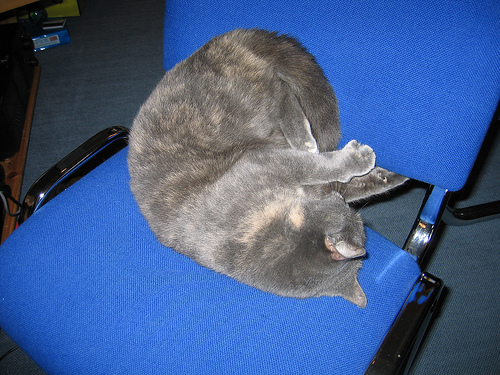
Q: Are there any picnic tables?
A: No, there are no picnic tables.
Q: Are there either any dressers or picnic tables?
A: No, there are no picnic tables or dressers.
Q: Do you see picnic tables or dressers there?
A: No, there are no picnic tables or dressers.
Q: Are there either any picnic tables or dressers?
A: No, there are no picnic tables or dressers.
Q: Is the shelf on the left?
A: Yes, the shelf is on the left of the image.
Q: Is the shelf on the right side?
A: No, the shelf is on the left of the image.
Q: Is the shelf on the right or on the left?
A: The shelf is on the left of the image.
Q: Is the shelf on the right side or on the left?
A: The shelf is on the left of the image.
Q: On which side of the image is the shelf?
A: The shelf is on the left of the image.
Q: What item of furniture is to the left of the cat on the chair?
A: The piece of furniture is a shelf.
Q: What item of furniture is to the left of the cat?
A: The piece of furniture is a shelf.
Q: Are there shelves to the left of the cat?
A: Yes, there is a shelf to the left of the cat.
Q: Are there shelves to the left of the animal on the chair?
A: Yes, there is a shelf to the left of the cat.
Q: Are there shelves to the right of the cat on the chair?
A: No, the shelf is to the left of the cat.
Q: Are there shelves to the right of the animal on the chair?
A: No, the shelf is to the left of the cat.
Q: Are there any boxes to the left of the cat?
A: No, there is a shelf to the left of the cat.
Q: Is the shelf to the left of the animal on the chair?
A: Yes, the shelf is to the left of the cat.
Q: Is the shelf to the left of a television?
A: No, the shelf is to the left of the cat.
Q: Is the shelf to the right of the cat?
A: No, the shelf is to the left of the cat.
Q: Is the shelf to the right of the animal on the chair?
A: No, the shelf is to the left of the cat.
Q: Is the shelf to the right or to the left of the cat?
A: The shelf is to the left of the cat.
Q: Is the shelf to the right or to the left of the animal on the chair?
A: The shelf is to the left of the cat.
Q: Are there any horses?
A: No, there are no horses.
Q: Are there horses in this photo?
A: No, there are no horses.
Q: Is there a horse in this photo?
A: No, there are no horses.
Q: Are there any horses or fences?
A: No, there are no horses or fences.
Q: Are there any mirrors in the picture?
A: No, there are no mirrors.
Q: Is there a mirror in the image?
A: No, there are no mirrors.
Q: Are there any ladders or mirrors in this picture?
A: No, there are no mirrors or ladders.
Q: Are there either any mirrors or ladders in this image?
A: No, there are no mirrors or ladders.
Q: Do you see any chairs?
A: Yes, there is a chair.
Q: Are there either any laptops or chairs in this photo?
A: Yes, there is a chair.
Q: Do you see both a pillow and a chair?
A: No, there is a chair but no pillows.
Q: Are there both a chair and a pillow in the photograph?
A: No, there is a chair but no pillows.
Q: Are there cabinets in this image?
A: No, there are no cabinets.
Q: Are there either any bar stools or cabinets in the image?
A: No, there are no cabinets or bar stools.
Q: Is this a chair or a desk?
A: This is a chair.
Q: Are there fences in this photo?
A: No, there are no fences.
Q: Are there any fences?
A: No, there are no fences.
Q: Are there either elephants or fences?
A: No, there are no fences or elephants.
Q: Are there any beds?
A: No, there are no beds.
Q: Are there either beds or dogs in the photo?
A: No, there are no beds or dogs.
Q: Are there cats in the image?
A: Yes, there is a cat.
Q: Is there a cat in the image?
A: Yes, there is a cat.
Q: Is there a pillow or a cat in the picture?
A: Yes, there is a cat.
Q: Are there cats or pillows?
A: Yes, there is a cat.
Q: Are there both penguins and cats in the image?
A: No, there is a cat but no penguins.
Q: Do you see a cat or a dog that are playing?
A: Yes, the cat is playing.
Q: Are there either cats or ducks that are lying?
A: Yes, the cat is lying.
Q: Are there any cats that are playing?
A: Yes, there is a cat that is playing.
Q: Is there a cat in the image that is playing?
A: Yes, there is a cat that is playing.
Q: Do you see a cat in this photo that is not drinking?
A: Yes, there is a cat that is playing .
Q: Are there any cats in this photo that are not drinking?
A: Yes, there is a cat that is playing.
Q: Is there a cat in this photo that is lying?
A: Yes, there is a cat that is lying.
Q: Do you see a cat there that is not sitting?
A: Yes, there is a cat that is lying .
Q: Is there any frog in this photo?
A: No, there are no frogs.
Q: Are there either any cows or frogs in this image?
A: No, there are no frogs or cows.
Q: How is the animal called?
A: The animal is a cat.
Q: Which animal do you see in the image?
A: The animal is a cat.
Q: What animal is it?
A: The animal is a cat.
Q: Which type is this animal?
A: That is a cat.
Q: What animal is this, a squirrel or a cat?
A: That is a cat.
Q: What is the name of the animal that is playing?
A: The animal is a cat.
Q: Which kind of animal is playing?
A: The animal is a cat.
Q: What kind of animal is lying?
A: The animal is a cat.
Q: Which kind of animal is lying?
A: The animal is a cat.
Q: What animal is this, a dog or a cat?
A: This is a cat.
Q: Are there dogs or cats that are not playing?
A: No, there is a cat but it is playing.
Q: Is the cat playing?
A: Yes, the cat is playing.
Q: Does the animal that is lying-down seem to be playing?
A: Yes, the cat is playing.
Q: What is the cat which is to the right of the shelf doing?
A: The cat is playing.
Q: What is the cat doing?
A: The cat is playing.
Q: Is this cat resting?
A: No, the cat is playing.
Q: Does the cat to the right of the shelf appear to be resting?
A: No, the cat is playing.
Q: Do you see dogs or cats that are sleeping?
A: No, there is a cat but it is playing.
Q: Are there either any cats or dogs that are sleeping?
A: No, there is a cat but it is playing.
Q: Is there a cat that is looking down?
A: No, there is a cat but it is playing.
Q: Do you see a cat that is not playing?
A: No, there is a cat but it is playing.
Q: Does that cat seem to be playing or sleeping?
A: The cat is playing.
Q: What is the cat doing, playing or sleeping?
A: The cat is playing.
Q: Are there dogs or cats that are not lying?
A: No, there is a cat but it is lying.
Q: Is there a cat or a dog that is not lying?
A: No, there is a cat but it is lying.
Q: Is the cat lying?
A: Yes, the cat is lying.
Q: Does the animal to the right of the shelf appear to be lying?
A: Yes, the cat is lying.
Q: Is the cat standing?
A: No, the cat is lying.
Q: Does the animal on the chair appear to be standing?
A: No, the cat is lying.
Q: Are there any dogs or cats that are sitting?
A: No, there is a cat but it is lying.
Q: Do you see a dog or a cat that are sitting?
A: No, there is a cat but it is lying.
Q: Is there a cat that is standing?
A: No, there is a cat but it is lying.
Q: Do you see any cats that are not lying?
A: No, there is a cat but it is lying.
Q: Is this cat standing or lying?
A: The cat is lying.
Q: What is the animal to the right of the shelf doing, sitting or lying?
A: The cat is lying.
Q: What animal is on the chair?
A: The cat is on the chair.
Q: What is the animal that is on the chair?
A: The animal is a cat.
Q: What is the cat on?
A: The cat is on the chair.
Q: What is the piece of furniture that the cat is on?
A: The piece of furniture is a chair.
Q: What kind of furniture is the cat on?
A: The cat is on the chair.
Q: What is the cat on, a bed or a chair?
A: The cat is on a chair.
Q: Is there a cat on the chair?
A: Yes, there is a cat on the chair.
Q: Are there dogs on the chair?
A: No, there is a cat on the chair.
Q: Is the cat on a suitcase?
A: No, the cat is on the chair.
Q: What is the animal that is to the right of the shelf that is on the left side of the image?
A: The animal is a cat.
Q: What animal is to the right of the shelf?
A: The animal is a cat.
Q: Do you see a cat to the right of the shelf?
A: Yes, there is a cat to the right of the shelf.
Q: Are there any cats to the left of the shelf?
A: No, the cat is to the right of the shelf.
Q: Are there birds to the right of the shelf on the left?
A: No, there is a cat to the right of the shelf.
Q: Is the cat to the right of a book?
A: No, the cat is to the right of a shelf.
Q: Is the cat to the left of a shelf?
A: No, the cat is to the right of a shelf.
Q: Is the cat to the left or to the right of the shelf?
A: The cat is to the right of the shelf.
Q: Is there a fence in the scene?
A: No, there are no fences.